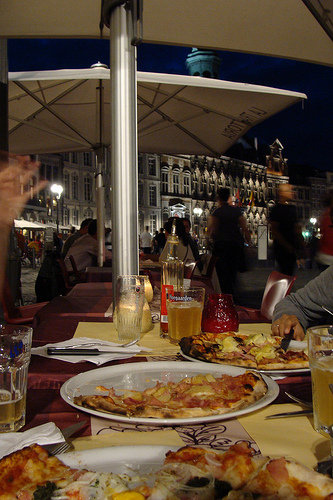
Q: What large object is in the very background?
A: Building.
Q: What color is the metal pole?
A: Silver.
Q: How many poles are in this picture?
A: Two.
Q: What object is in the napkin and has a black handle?
A: Knife.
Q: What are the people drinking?
A: Beer.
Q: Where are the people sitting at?
A: Under the umbrella.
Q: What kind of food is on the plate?
A: Pizza.